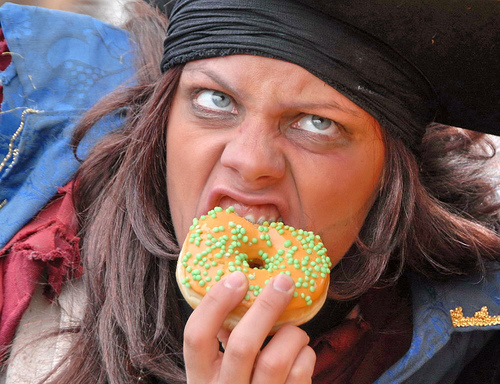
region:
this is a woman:
[161, 55, 387, 236]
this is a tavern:
[212, 9, 497, 52]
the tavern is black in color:
[179, 5, 496, 50]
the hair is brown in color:
[101, 153, 163, 382]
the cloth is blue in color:
[13, 24, 97, 106]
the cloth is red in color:
[36, 215, 79, 279]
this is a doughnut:
[191, 228, 311, 275]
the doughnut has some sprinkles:
[213, 227, 258, 270]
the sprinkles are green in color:
[285, 240, 317, 269]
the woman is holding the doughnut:
[180, 214, 322, 381]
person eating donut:
[0, 0, 497, 380]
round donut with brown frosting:
[170, 204, 330, 330]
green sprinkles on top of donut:
[180, 205, 331, 305]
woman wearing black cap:
[146, 1, 498, 142]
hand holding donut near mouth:
[178, 270, 319, 382]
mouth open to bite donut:
[201, 184, 287, 232]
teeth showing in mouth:
[233, 211, 284, 226]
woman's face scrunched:
[163, 55, 385, 270]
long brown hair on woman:
[4, 1, 498, 381]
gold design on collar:
[448, 303, 498, 328]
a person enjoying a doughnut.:
[60, 22, 465, 362]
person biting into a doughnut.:
[40, 33, 471, 345]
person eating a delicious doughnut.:
[42, 19, 457, 346]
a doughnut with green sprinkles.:
[172, 214, 344, 323]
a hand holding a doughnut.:
[150, 233, 353, 372]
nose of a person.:
[222, 126, 288, 185]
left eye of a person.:
[284, 102, 358, 149]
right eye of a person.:
[181, 66, 245, 133]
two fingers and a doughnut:
[176, 221, 326, 315]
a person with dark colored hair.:
[37, 21, 464, 331]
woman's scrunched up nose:
[215, 100, 295, 186]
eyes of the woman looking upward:
[183, 84, 365, 150]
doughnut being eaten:
[180, 188, 352, 333]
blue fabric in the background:
[1, 5, 133, 311]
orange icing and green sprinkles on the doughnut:
[170, 194, 343, 327]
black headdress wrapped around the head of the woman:
[150, 0, 458, 155]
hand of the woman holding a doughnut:
[160, 268, 342, 381]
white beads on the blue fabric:
[2, 80, 44, 219]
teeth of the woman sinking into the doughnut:
[211, 197, 291, 231]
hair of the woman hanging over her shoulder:
[65, 63, 172, 377]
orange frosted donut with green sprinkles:
[170, 190, 349, 331]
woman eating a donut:
[100, 40, 427, 351]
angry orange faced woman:
[128, 54, 400, 329]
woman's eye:
[185, 82, 251, 127]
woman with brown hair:
[48, 19, 435, 380]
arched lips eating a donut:
[154, 182, 353, 369]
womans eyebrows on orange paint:
[137, 55, 412, 171]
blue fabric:
[7, 20, 130, 235]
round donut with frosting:
[180, 190, 349, 350]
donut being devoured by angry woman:
[127, 37, 399, 347]